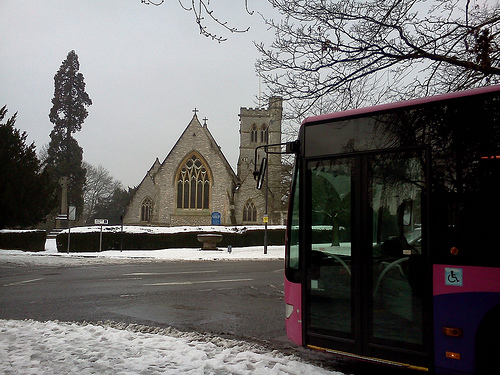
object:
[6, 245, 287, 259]
snow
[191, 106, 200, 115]
cross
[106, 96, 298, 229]
church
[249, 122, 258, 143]
window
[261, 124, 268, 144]
window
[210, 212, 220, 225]
door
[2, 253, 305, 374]
road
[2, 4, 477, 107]
sky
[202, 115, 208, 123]
cross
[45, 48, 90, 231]
tree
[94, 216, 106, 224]
sign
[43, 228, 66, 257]
steps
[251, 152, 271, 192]
mirror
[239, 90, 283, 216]
tower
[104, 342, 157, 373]
snow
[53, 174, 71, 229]
monument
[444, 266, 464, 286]
symbol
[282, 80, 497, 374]
bus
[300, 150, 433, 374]
doors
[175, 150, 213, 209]
window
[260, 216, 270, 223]
sign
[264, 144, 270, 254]
pole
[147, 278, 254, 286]
markings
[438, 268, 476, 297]
sign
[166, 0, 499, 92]
branches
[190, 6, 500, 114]
trees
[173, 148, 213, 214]
arched window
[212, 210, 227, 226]
sign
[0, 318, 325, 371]
snow